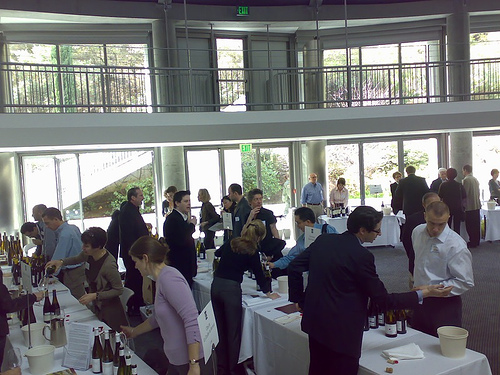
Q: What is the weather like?
A: It is sunny.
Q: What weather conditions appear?
A: It is sunny.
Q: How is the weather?
A: It is sunny.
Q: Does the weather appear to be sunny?
A: Yes, it is sunny.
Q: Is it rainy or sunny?
A: It is sunny.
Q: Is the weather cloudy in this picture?
A: No, it is sunny.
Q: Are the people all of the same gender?
A: No, they are both male and female.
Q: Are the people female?
A: No, they are both male and female.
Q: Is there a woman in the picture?
A: Yes, there is a woman.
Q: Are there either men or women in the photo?
A: Yes, there is a woman.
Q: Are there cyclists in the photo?
A: No, there are no cyclists.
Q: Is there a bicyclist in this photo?
A: No, there are no cyclists.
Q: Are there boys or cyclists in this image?
A: No, there are no cyclists or boys.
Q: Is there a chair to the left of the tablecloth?
A: No, there is a woman to the left of the tablecloth.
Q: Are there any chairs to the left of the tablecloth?
A: No, there is a woman to the left of the tablecloth.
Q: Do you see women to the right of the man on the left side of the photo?
A: Yes, there is a woman to the right of the man.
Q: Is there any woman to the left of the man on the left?
A: No, the woman is to the right of the man.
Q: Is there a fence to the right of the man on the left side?
A: No, there is a woman to the right of the man.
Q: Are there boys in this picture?
A: No, there are no boys.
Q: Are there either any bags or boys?
A: No, there are no boys or bags.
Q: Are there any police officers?
A: No, there are no police officers.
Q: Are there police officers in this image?
A: No, there are no police officers.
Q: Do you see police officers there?
A: No, there are no police officers.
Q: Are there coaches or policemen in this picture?
A: No, there are no policemen or coaches.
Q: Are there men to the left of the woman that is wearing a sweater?
A: Yes, there is a man to the left of the woman.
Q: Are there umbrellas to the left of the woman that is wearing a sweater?
A: No, there is a man to the left of the woman.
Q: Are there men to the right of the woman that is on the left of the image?
A: Yes, there is a man to the right of the woman.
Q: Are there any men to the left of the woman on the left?
A: No, the man is to the right of the woman.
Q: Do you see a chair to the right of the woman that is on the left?
A: No, there is a man to the right of the woman.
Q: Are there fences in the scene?
A: No, there are no fences.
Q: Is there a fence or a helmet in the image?
A: No, there are no fences or helmets.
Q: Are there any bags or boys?
A: No, there are no boys or bags.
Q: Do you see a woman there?
A: Yes, there is a woman.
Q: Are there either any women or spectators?
A: Yes, there is a woman.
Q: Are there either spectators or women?
A: Yes, there is a woman.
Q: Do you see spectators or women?
A: Yes, there is a woman.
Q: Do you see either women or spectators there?
A: Yes, there is a woman.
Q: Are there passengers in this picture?
A: No, there are no passengers.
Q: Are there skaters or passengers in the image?
A: No, there are no passengers or skaters.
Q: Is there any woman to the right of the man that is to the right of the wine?
A: Yes, there is a woman to the right of the man.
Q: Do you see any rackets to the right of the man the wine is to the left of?
A: No, there is a woman to the right of the man.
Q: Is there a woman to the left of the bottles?
A: Yes, there is a woman to the left of the bottles.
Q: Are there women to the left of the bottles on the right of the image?
A: Yes, there is a woman to the left of the bottles.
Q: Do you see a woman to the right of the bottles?
A: No, the woman is to the left of the bottles.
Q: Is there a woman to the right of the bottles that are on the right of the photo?
A: No, the woman is to the left of the bottles.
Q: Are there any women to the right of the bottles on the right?
A: No, the woman is to the left of the bottles.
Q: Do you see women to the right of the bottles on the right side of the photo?
A: No, the woman is to the left of the bottles.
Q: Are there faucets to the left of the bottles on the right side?
A: No, there is a woman to the left of the bottles.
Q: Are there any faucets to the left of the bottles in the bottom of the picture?
A: No, there is a woman to the left of the bottles.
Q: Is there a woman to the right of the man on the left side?
A: Yes, there is a woman to the right of the man.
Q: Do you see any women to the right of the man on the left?
A: Yes, there is a woman to the right of the man.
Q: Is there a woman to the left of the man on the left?
A: No, the woman is to the right of the man.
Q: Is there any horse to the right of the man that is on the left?
A: No, there is a woman to the right of the man.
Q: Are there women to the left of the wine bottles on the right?
A: Yes, there is a woman to the left of the wine bottles.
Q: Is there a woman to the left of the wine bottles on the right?
A: Yes, there is a woman to the left of the wine bottles.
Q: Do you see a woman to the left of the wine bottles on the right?
A: Yes, there is a woman to the left of the wine bottles.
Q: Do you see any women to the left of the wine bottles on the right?
A: Yes, there is a woman to the left of the wine bottles.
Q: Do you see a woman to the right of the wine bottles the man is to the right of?
A: No, the woman is to the left of the wine bottles.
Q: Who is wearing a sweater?
A: The woman is wearing a sweater.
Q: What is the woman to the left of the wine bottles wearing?
A: The woman is wearing a sweater.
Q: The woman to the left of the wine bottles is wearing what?
A: The woman is wearing a sweater.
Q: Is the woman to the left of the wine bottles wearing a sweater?
A: Yes, the woman is wearing a sweater.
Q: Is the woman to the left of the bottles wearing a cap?
A: No, the woman is wearing a sweater.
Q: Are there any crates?
A: No, there are no crates.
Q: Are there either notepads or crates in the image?
A: No, there are no crates or notepads.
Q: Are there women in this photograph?
A: Yes, there is a woman.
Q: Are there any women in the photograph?
A: Yes, there is a woman.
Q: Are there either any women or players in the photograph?
A: Yes, there is a woman.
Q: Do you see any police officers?
A: No, there are no police officers.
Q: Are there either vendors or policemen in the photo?
A: No, there are no policemen or vendors.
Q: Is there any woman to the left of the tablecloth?
A: Yes, there is a woman to the left of the tablecloth.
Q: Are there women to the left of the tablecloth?
A: Yes, there is a woman to the left of the tablecloth.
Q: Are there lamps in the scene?
A: No, there are no lamps.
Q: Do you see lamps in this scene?
A: No, there are no lamps.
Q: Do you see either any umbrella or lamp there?
A: No, there are no lamps or umbrellas.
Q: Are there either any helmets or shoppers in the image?
A: No, there are no helmets or shoppers.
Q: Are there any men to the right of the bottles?
A: Yes, there is a man to the right of the bottles.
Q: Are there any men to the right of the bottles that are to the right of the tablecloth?
A: Yes, there is a man to the right of the bottles.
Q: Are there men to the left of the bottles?
A: No, the man is to the right of the bottles.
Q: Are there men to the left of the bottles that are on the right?
A: No, the man is to the right of the bottles.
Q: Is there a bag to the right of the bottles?
A: No, there is a man to the right of the bottles.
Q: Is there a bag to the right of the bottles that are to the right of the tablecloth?
A: No, there is a man to the right of the bottles.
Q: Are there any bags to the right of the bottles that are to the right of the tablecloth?
A: No, there is a man to the right of the bottles.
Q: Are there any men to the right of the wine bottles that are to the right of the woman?
A: Yes, there is a man to the right of the wine bottles.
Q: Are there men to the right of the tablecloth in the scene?
A: Yes, there is a man to the right of the tablecloth.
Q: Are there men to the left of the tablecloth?
A: No, the man is to the right of the tablecloth.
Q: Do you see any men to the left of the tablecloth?
A: No, the man is to the right of the tablecloth.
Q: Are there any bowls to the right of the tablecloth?
A: No, there is a man to the right of the tablecloth.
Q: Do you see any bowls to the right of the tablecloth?
A: No, there is a man to the right of the tablecloth.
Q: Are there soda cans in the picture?
A: No, there are no soda cans.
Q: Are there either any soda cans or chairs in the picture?
A: No, there are no soda cans or chairs.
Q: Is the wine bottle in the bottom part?
A: Yes, the wine bottle is in the bottom of the image.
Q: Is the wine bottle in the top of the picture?
A: No, the wine bottle is in the bottom of the image.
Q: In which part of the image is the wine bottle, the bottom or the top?
A: The wine bottle is in the bottom of the image.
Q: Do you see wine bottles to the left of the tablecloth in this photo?
A: Yes, there is a wine bottle to the left of the tablecloth.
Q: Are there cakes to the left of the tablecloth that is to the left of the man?
A: No, there is a wine bottle to the left of the tablecloth.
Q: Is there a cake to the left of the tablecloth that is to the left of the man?
A: No, there is a wine bottle to the left of the tablecloth.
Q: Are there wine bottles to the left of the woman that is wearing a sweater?
A: Yes, there is a wine bottle to the left of the woman.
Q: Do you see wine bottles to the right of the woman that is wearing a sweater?
A: No, the wine bottle is to the left of the woman.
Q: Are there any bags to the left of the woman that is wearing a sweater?
A: No, there is a wine bottle to the left of the woman.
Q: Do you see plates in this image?
A: No, there are no plates.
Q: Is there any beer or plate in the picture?
A: No, there are no plates or beer.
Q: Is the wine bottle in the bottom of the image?
A: Yes, the wine bottle is in the bottom of the image.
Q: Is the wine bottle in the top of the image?
A: No, the wine bottle is in the bottom of the image.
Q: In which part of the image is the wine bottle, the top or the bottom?
A: The wine bottle is in the bottom of the image.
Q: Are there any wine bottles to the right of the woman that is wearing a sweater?
A: No, the wine bottle is to the left of the woman.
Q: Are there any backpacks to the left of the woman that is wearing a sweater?
A: No, there is a wine bottle to the left of the woman.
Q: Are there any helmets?
A: No, there are no helmets.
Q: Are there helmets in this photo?
A: No, there are no helmets.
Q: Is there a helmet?
A: No, there are no helmets.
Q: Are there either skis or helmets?
A: No, there are no helmets or skis.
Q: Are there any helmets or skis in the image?
A: No, there are no helmets or skis.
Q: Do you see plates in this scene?
A: No, there are no plates.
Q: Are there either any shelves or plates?
A: No, there are no plates or shelves.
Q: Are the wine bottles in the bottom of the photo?
A: Yes, the wine bottles are in the bottom of the image.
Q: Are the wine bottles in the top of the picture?
A: No, the wine bottles are in the bottom of the image.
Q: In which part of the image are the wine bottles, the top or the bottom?
A: The wine bottles are in the bottom of the image.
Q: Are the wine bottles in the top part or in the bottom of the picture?
A: The wine bottles are in the bottom of the image.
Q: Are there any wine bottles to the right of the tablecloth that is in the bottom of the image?
A: Yes, there are wine bottles to the right of the tablecloth.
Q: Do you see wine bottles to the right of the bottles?
A: Yes, there are wine bottles to the right of the bottles.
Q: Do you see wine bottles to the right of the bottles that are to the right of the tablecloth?
A: Yes, there are wine bottles to the right of the bottles.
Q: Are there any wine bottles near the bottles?
A: Yes, there are wine bottles near the bottles.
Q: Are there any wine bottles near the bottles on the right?
A: Yes, there are wine bottles near the bottles.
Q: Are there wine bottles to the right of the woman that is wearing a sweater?
A: Yes, there are wine bottles to the right of the woman.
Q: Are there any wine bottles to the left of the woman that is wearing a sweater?
A: No, the wine bottles are to the right of the woman.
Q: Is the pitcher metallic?
A: Yes, the pitcher is metallic.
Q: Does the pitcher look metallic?
A: Yes, the pitcher is metallic.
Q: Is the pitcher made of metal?
A: Yes, the pitcher is made of metal.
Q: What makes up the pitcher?
A: The pitcher is made of metal.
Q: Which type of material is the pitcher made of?
A: The pitcher is made of metal.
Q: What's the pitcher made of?
A: The pitcher is made of metal.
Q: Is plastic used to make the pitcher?
A: No, the pitcher is made of metal.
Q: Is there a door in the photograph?
A: Yes, there is a door.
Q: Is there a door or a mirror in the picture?
A: Yes, there is a door.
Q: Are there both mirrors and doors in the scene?
A: No, there is a door but no mirrors.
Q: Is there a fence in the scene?
A: No, there are no fences.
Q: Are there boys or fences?
A: No, there are no fences or boys.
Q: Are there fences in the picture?
A: No, there are no fences.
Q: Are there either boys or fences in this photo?
A: No, there are no fences or boys.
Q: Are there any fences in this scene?
A: No, there are no fences.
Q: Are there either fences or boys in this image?
A: No, there are no fences or boys.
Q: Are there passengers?
A: No, there are no passengers.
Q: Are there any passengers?
A: No, there are no passengers.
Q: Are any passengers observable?
A: No, there are no passengers.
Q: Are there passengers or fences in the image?
A: No, there are no passengers or fences.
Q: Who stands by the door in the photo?
A: The man stands by the door.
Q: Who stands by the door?
A: The man stands by the door.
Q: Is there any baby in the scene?
A: No, there are no babies.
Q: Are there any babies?
A: No, there are no babies.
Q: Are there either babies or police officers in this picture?
A: No, there are no babies or police officers.